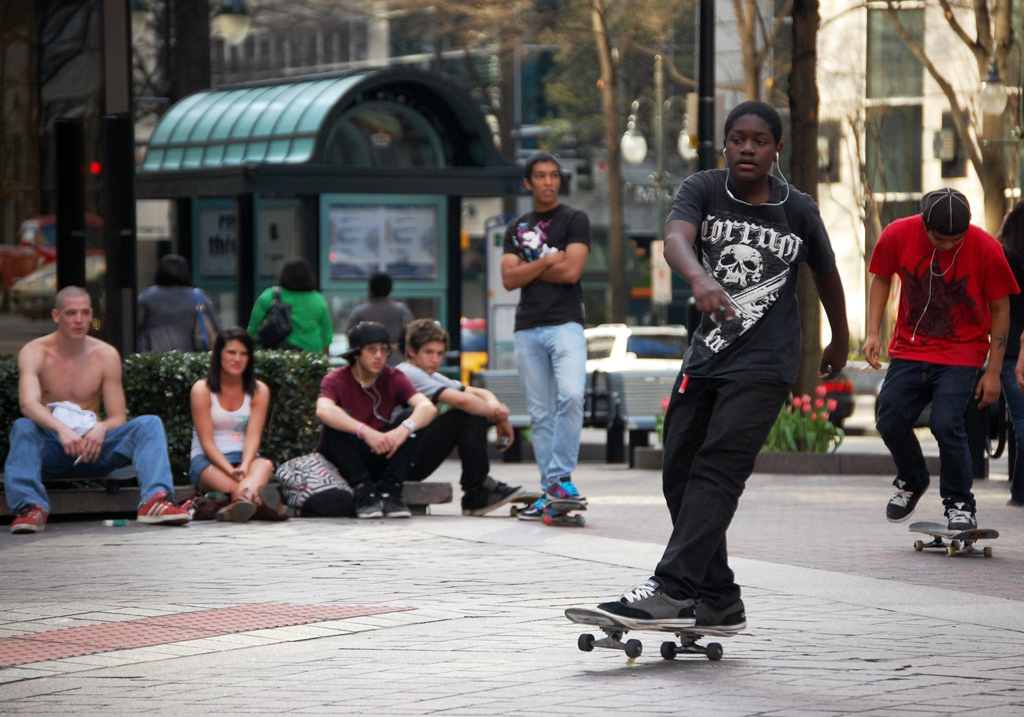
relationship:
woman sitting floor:
[190, 328, 298, 520] [9, 487, 952, 714]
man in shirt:
[388, 317, 522, 518] [390, 360, 467, 430]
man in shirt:
[388, 317, 522, 518] [385, 362, 468, 438]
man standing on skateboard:
[496, 147, 595, 512] [510, 494, 588, 527]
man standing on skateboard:
[496, 147, 595, 512] [512, 490, 589, 525]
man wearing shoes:
[4, 283, 188, 540] [7, 500, 46, 535]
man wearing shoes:
[4, 283, 188, 540] [133, 493, 194, 522]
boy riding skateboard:
[592, 93, 856, 629] [557, 602, 748, 661]